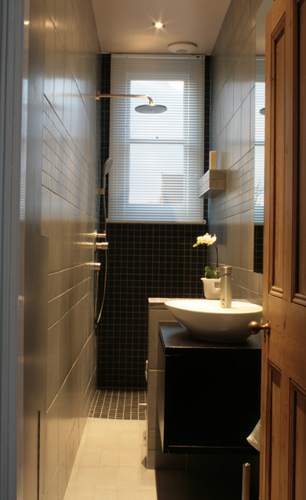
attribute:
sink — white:
[159, 286, 265, 339]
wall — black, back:
[110, 226, 193, 292]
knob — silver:
[95, 240, 108, 248]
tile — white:
[98, 445, 119, 467]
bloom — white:
[193, 232, 216, 246]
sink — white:
[162, 295, 261, 346]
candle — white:
[208, 147, 218, 171]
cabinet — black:
[242, 40, 304, 342]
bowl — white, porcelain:
[172, 282, 251, 346]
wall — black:
[52, 64, 103, 133]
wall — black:
[134, 231, 189, 281]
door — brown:
[257, 1, 302, 390]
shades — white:
[103, 50, 209, 227]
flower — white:
[193, 231, 217, 246]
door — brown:
[259, 0, 304, 498]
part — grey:
[87, 386, 144, 420]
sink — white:
[160, 263, 261, 345]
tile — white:
[97, 449, 134, 486]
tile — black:
[96, 52, 208, 388]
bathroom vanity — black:
[144, 316, 293, 480]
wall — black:
[95, 50, 212, 390]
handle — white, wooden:
[241, 462, 251, 499]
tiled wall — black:
[1, 0, 103, 498]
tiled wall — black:
[204, 2, 253, 293]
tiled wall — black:
[100, 225, 201, 404]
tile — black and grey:
[112, 274, 139, 376]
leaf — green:
[193, 241, 227, 280]